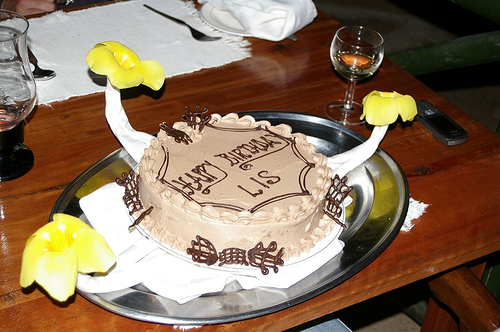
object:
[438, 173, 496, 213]
table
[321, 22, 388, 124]
wine glass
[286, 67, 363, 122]
table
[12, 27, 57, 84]
spoon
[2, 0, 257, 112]
place mat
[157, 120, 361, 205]
cake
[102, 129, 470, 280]
platter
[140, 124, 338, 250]
cake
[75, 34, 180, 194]
flower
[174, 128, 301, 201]
lettering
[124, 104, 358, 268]
cake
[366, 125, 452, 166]
ground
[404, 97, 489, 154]
cellphone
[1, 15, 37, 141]
glass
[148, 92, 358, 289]
cake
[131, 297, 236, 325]
silver platter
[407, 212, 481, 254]
table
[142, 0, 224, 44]
fork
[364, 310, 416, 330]
carpet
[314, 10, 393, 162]
glass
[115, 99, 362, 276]
cake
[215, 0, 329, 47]
napkin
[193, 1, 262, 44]
plate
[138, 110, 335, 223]
ribbon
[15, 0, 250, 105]
cloth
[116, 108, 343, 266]
cake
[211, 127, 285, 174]
writing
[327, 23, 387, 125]
glass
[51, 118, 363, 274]
cake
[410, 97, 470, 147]
phone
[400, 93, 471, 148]
cell phone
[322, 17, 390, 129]
glass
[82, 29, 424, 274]
cake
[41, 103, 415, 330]
pan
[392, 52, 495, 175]
table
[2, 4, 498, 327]
room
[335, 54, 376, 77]
liquid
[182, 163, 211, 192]
word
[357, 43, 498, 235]
table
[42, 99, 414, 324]
platter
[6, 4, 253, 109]
mat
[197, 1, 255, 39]
plate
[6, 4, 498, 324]
table